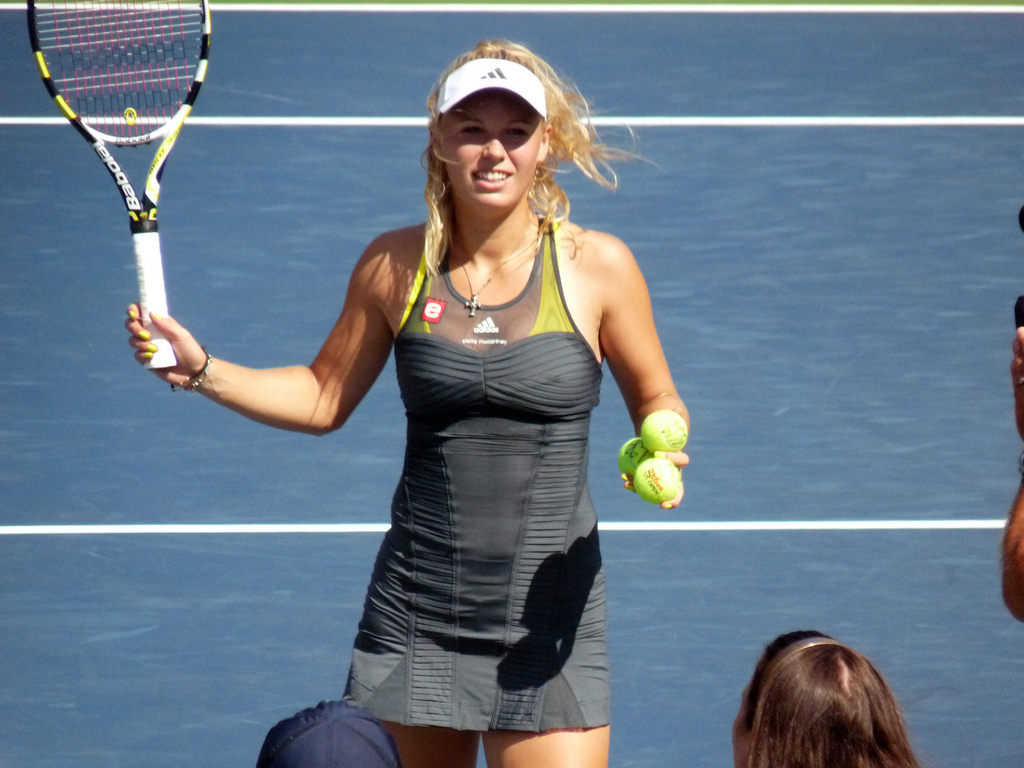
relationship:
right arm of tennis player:
[222, 276, 404, 465] [117, 26, 697, 763]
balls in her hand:
[629, 455, 684, 503] [601, 414, 697, 521]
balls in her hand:
[636, 406, 693, 454] [598, 410, 705, 517]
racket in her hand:
[19, 5, 221, 369] [120, 302, 211, 389]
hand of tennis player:
[120, 302, 211, 389] [117, 26, 697, 763]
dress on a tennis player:
[318, 216, 641, 744] [117, 26, 697, 763]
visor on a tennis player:
[415, 52, 545, 119] [117, 26, 697, 763]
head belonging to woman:
[728, 625, 925, 764] [722, 627, 917, 761]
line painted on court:
[0, 518, 1005, 535] [0, 0, 1024, 767]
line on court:
[0, 518, 1005, 534] [8, 1, 1015, 762]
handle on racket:
[125, 230, 177, 367] [19, 5, 221, 369]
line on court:
[0, 518, 1005, 535] [0, 0, 1024, 767]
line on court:
[0, 113, 1022, 129] [0, 0, 1024, 767]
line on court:
[0, 5, 1022, 12] [0, 0, 1024, 767]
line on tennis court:
[0, 518, 1005, 535] [0, 510, 1018, 541]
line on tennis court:
[0, 113, 1022, 130] [0, 510, 1018, 541]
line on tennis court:
[0, 5, 1022, 12] [0, 510, 1018, 541]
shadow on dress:
[488, 515, 614, 691] [336, 216, 621, 744]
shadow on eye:
[426, 91, 541, 152] [493, 119, 535, 145]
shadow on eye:
[426, 91, 541, 152] [454, 119, 491, 146]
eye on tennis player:
[493, 119, 535, 145] [117, 26, 697, 763]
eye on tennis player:
[454, 119, 491, 146] [117, 26, 697, 763]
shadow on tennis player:
[426, 91, 541, 152] [117, 26, 697, 763]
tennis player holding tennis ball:
[117, 26, 697, 763] [620, 435, 683, 496]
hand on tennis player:
[603, 437, 703, 515] [117, 26, 697, 763]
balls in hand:
[616, 402, 697, 504] [603, 437, 703, 515]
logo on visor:
[466, 55, 516, 84] [428, 50, 554, 124]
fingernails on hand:
[132, 324, 158, 364] [119, 303, 210, 390]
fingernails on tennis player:
[132, 324, 158, 364] [117, 26, 697, 763]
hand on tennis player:
[119, 303, 210, 390] [117, 26, 697, 763]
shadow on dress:
[488, 515, 614, 691] [337, 212, 616, 731]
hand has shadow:
[603, 434, 701, 515] [488, 515, 614, 691]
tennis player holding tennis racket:
[117, 26, 697, 763] [121, 35, 692, 764]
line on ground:
[0, 518, 1005, 535] [0, 0, 1024, 768]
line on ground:
[0, 113, 1022, 130] [0, 0, 1024, 768]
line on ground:
[0, 5, 1022, 12] [0, 0, 1024, 768]